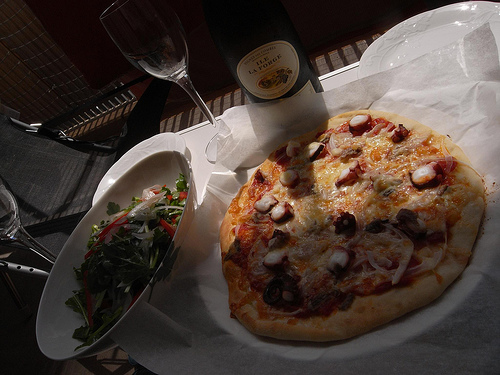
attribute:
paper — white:
[112, 25, 497, 374]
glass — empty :
[100, 1, 242, 161]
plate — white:
[357, 0, 499, 89]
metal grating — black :
[63, 97, 140, 126]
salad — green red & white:
[56, 142, 218, 362]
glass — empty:
[1, 180, 63, 285]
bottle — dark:
[203, 1, 318, 111]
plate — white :
[357, 10, 494, 65]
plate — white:
[67, 126, 222, 249]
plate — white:
[194, 276, 217, 316]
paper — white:
[397, 69, 487, 126]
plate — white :
[357, 0, 498, 80]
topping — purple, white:
[346, 112, 373, 135]